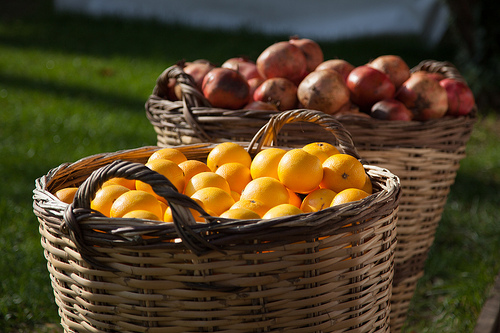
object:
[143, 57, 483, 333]
basket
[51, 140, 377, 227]
food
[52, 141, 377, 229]
fruit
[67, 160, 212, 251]
handle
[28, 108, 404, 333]
basket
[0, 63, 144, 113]
shadow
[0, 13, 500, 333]
ground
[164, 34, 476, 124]
food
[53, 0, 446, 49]
wall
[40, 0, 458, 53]
building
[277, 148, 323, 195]
lemon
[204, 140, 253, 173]
lemon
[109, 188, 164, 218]
lemon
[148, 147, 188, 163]
lemon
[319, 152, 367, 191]
lemon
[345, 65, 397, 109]
potato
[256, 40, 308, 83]
potato